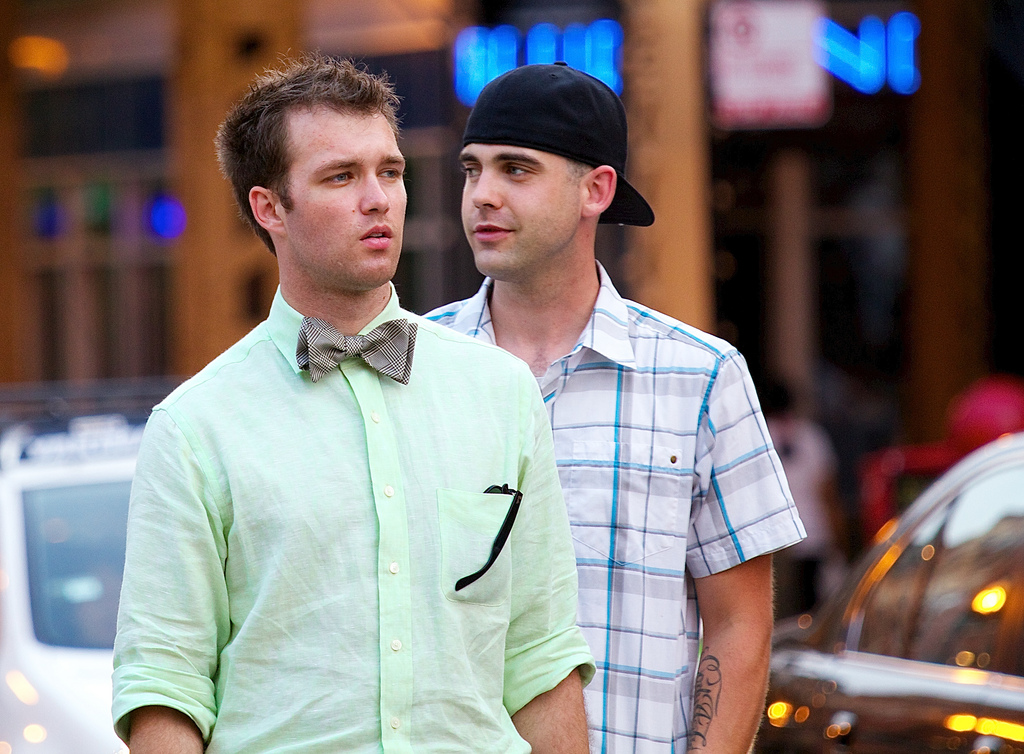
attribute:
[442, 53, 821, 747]
man — white, plaid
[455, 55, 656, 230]
hat — black, on backwards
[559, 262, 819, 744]
shirt — blue and white plaid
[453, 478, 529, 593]
glasses — black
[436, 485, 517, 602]
pocket — shirt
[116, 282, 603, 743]
shirt — button down, green, button up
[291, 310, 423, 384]
bow tie — black and white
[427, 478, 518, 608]
pocket — shirt's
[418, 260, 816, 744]
shirt — short sleeve, plaid pattern, blue, white, striped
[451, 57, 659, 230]
cap — black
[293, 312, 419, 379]
bow tie — black, white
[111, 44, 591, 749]
man — green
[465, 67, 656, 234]
hat — black, backwards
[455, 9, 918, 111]
neon lights — blue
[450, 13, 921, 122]
sign — blue neon, blurry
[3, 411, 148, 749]
car — white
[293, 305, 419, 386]
bowtie — black, white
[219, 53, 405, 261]
hair — brown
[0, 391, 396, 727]
vehicle — white